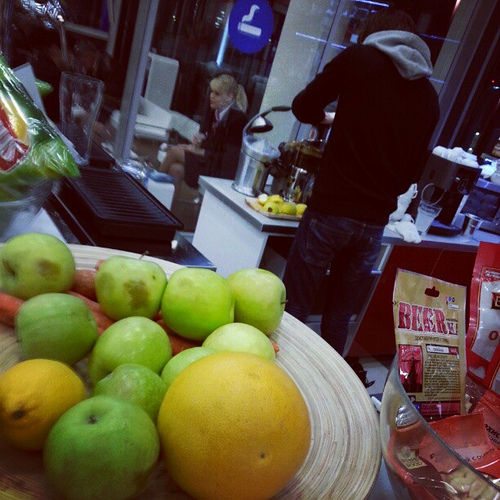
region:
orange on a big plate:
[158, 345, 318, 497]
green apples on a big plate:
[5, 223, 307, 498]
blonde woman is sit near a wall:
[151, 66, 254, 194]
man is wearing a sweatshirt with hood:
[260, 3, 457, 332]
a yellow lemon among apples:
[3, 351, 93, 461]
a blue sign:
[217, 0, 287, 60]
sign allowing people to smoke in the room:
[215, 3, 276, 55]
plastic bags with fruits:
[3, 55, 98, 198]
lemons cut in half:
[248, 183, 310, 225]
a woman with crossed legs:
[157, 65, 257, 192]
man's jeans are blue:
[282, 197, 382, 365]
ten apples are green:
[0, 234, 288, 499]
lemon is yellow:
[2, 354, 89, 451]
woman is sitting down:
[151, 73, 249, 186]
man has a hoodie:
[353, 34, 438, 82]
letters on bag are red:
[397, 299, 448, 336]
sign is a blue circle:
[227, 3, 276, 54]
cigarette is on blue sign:
[226, 0, 280, 51]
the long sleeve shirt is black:
[288, 43, 441, 221]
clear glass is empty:
[58, 71, 108, 167]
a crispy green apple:
[234, 263, 286, 331]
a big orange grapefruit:
[155, 351, 312, 499]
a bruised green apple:
[0, 232, 77, 296]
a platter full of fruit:
[1, 232, 378, 499]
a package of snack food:
[390, 238, 467, 420]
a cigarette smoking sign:
[227, 1, 277, 55]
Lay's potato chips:
[0, 65, 80, 199]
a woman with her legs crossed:
[154, 72, 248, 179]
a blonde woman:
[155, 75, 247, 170]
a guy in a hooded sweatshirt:
[291, 1, 442, 356]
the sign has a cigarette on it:
[223, 0, 285, 65]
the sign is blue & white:
[231, 0, 281, 56]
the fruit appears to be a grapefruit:
[150, 345, 342, 494]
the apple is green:
[44, 389, 170, 491]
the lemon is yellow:
[0, 348, 100, 443]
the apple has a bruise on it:
[13, 227, 82, 287]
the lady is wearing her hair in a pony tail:
[194, 62, 259, 126]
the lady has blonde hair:
[207, 55, 299, 126]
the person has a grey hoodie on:
[367, 15, 449, 97]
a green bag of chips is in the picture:
[0, 67, 119, 223]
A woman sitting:
[159, 65, 252, 203]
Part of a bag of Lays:
[0, 56, 91, 224]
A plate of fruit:
[2, 228, 318, 498]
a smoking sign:
[210, 0, 273, 57]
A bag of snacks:
[389, 262, 463, 429]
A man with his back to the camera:
[289, 13, 446, 359]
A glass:
[412, 195, 439, 242]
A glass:
[51, 60, 106, 177]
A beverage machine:
[430, 141, 483, 249]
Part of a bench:
[114, 91, 173, 147]